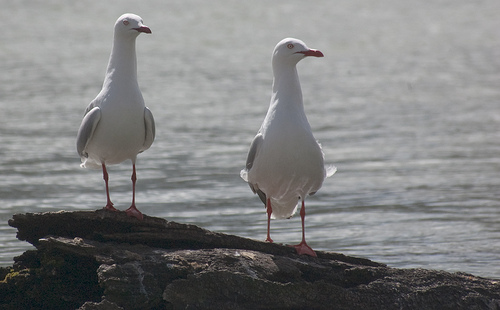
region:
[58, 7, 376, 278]
there are two birds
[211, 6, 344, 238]
the bird is white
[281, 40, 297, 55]
the birds eye is yellow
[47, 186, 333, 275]
the birds are standing on the rocks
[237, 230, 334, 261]
the birds feet are webbed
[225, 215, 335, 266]
the feet are orange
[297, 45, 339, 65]
the beak is orange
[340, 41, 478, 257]
the water is calm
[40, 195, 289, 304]
the rocks are brown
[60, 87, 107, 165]
the wing is grey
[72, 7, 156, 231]
sea gull looking to the left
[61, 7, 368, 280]
sea gulls looking to the left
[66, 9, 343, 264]
pair of seagulls on a rock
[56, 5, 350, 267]
pair of seagulls at the shore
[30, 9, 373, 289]
seagull duo near water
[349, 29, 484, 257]
wind blown choppy water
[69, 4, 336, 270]
white sea birds on a rock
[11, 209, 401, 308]
rocks near body of water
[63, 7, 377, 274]
two seagulls looking to the left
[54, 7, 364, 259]
pair of alert seagulls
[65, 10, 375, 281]
two white and grey seagulls perched on a rock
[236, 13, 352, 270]
white and grey seagull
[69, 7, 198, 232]
white and grey seagull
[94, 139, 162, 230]
orange legs of a seagull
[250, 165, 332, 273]
orange legs of a seagull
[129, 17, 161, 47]
beak of a seagull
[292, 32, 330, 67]
beak of a seagull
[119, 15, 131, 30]
eye of a seagull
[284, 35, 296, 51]
eye of a seagull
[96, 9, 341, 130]
water behind two seagulls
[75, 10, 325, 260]
two white and gray birds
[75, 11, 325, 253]
two birds standing on top of a black log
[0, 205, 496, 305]
a rotten log on the shore of a beach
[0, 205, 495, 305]
a wooden log on the ocean shore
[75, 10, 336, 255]
two white birds with red legs and feet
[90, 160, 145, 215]
red legs and feet on the bird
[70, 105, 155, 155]
two gray wings on the bird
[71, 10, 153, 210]
a white bird standing behind another white bird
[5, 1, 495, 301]
white and gray birds standing on top of rotten log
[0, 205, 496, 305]
a black decayed log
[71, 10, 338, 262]
two gulls looking right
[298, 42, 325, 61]
the beak of a gull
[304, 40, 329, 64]
the beak of a bird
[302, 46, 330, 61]
the bill of a bird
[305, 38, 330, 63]
the bill of a gull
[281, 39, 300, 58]
eye of a gull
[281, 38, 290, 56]
eye of a bird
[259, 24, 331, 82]
head of a sea gull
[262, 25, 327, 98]
head of a gull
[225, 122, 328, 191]
chest of a sea gull